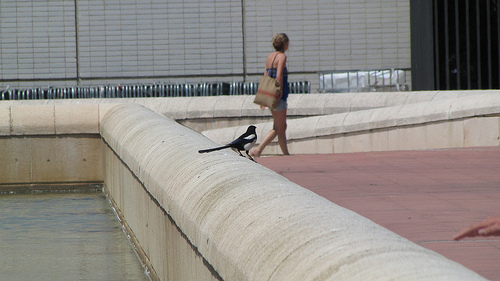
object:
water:
[0, 190, 163, 280]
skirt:
[263, 51, 293, 101]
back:
[266, 51, 285, 73]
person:
[248, 32, 296, 156]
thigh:
[273, 107, 287, 131]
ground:
[251, 147, 500, 280]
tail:
[198, 144, 228, 155]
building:
[0, 0, 434, 98]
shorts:
[268, 99, 283, 111]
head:
[246, 124, 258, 133]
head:
[273, 32, 291, 49]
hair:
[271, 32, 289, 51]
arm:
[277, 53, 287, 98]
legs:
[256, 105, 284, 150]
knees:
[274, 123, 287, 133]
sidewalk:
[245, 146, 499, 281]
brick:
[200, 125, 237, 145]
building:
[0, 83, 492, 280]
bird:
[197, 124, 262, 164]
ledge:
[92, 96, 500, 279]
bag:
[250, 74, 287, 108]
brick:
[78, 73, 91, 76]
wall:
[0, 1, 409, 84]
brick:
[105, 66, 120, 72]